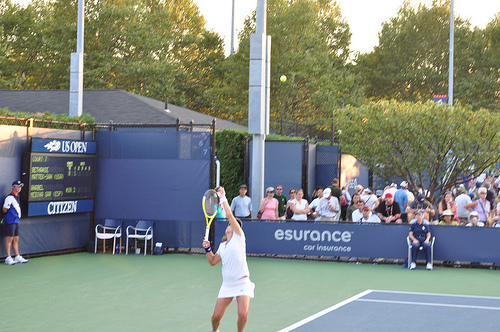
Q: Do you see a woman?
A: Yes, there is a woman.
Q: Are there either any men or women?
A: Yes, there is a woman.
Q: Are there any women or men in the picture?
A: Yes, there is a woman.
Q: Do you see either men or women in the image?
A: Yes, there is a woman.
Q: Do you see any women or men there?
A: Yes, there is a woman.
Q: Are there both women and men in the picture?
A: Yes, there are both a woman and a man.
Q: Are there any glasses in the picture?
A: No, there are no glasses.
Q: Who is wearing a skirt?
A: The woman is wearing a skirt.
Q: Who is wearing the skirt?
A: The woman is wearing a skirt.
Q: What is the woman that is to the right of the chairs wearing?
A: The woman is wearing a skirt.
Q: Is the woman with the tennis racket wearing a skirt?
A: Yes, the woman is wearing a skirt.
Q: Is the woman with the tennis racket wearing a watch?
A: No, the woman is wearing a skirt.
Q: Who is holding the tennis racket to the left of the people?
A: The woman is holding the tennis racket.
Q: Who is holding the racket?
A: The woman is holding the tennis racket.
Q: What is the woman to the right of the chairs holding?
A: The woman is holding the racket.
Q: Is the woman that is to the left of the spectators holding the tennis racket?
A: Yes, the woman is holding the tennis racket.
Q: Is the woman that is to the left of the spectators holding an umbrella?
A: No, the woman is holding the tennis racket.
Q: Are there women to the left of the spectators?
A: Yes, there is a woman to the left of the spectators.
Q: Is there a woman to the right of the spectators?
A: No, the woman is to the left of the spectators.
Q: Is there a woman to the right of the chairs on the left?
A: Yes, there is a woman to the right of the chairs.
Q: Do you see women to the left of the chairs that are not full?
A: No, the woman is to the right of the chairs.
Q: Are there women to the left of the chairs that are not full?
A: No, the woman is to the right of the chairs.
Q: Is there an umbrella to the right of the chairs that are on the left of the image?
A: No, there is a woman to the right of the chairs.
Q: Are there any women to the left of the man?
A: Yes, there is a woman to the left of the man.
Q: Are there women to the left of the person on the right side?
A: Yes, there is a woman to the left of the man.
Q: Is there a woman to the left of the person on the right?
A: Yes, there is a woman to the left of the man.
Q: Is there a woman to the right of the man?
A: No, the woman is to the left of the man.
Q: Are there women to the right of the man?
A: No, the woman is to the left of the man.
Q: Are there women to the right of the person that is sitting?
A: No, the woman is to the left of the man.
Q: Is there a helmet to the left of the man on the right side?
A: No, there is a woman to the left of the man.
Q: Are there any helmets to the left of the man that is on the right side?
A: No, there is a woman to the left of the man.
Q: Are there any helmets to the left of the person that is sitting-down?
A: No, there is a woman to the left of the man.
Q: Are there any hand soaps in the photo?
A: No, there are no hand soaps.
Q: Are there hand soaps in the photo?
A: No, there are no hand soaps.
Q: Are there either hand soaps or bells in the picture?
A: No, there are no hand soaps or bells.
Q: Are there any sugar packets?
A: No, there are no sugar packets.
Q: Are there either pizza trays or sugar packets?
A: No, there are no sugar packets or pizza trays.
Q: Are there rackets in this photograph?
A: Yes, there is a racket.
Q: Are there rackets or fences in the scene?
A: Yes, there is a racket.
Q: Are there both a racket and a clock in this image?
A: No, there is a racket but no clocks.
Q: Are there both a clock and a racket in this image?
A: No, there is a racket but no clocks.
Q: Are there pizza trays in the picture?
A: No, there are no pizza trays.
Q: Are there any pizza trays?
A: No, there are no pizza trays.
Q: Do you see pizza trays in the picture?
A: No, there are no pizza trays.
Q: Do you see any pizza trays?
A: No, there are no pizza trays.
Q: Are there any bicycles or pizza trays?
A: No, there are no pizza trays or bicycles.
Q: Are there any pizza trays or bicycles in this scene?
A: No, there are no pizza trays or bicycles.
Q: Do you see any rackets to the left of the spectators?
A: Yes, there is a racket to the left of the spectators.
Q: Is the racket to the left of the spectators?
A: Yes, the racket is to the left of the spectators.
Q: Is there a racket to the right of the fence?
A: Yes, there is a racket to the right of the fence.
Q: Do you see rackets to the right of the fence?
A: Yes, there is a racket to the right of the fence.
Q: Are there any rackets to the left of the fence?
A: No, the racket is to the right of the fence.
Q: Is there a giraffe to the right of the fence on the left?
A: No, there is a racket to the right of the fence.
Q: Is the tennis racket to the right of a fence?
A: Yes, the tennis racket is to the right of a fence.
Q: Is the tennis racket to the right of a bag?
A: No, the tennis racket is to the right of a fence.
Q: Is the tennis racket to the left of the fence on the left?
A: No, the tennis racket is to the right of the fence.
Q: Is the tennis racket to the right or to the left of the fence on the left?
A: The tennis racket is to the right of the fence.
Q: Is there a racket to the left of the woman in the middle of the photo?
A: Yes, there is a racket to the left of the woman.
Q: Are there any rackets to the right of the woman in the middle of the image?
A: No, the racket is to the left of the woman.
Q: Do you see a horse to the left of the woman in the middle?
A: No, there is a racket to the left of the woman.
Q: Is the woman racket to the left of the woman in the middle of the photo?
A: Yes, the racket is to the left of the woman.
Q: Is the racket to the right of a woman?
A: No, the racket is to the left of a woman.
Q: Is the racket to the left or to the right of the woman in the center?
A: The racket is to the left of the woman.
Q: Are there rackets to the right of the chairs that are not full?
A: Yes, there is a racket to the right of the chairs.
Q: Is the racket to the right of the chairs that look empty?
A: Yes, the racket is to the right of the chairs.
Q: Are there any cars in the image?
A: No, there are no cars.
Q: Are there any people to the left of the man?
A: Yes, there are people to the left of the man.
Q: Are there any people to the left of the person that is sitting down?
A: Yes, there are people to the left of the man.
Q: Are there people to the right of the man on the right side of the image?
A: No, the people are to the left of the man.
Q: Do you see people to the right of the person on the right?
A: No, the people are to the left of the man.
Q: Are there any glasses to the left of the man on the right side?
A: No, there are people to the left of the man.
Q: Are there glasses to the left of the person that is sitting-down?
A: No, there are people to the left of the man.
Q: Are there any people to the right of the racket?
A: Yes, there are people to the right of the racket.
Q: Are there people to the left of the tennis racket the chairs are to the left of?
A: No, the people are to the right of the racket.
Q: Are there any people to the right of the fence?
A: Yes, there are people to the right of the fence.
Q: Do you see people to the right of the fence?
A: Yes, there are people to the right of the fence.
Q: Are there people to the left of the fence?
A: No, the people are to the right of the fence.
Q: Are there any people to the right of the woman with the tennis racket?
A: Yes, there are people to the right of the woman.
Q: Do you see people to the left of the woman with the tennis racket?
A: No, the people are to the right of the woman.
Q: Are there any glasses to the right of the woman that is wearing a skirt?
A: No, there are people to the right of the woman.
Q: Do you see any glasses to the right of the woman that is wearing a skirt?
A: No, there are people to the right of the woman.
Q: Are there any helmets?
A: No, there are no helmets.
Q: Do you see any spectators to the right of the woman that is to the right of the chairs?
A: Yes, there are spectators to the right of the woman.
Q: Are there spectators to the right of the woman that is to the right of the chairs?
A: Yes, there are spectators to the right of the woman.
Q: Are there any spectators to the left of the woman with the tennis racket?
A: No, the spectators are to the right of the woman.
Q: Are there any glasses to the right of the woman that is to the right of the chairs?
A: No, there are spectators to the right of the woman.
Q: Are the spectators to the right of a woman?
A: Yes, the spectators are to the right of a woman.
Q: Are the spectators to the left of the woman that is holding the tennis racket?
A: No, the spectators are to the right of the woman.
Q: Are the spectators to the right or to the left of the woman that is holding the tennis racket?
A: The spectators are to the right of the woman.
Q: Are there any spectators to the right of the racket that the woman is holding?
A: Yes, there are spectators to the right of the tennis racket.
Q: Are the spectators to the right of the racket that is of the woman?
A: Yes, the spectators are to the right of the racket.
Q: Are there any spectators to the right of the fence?
A: Yes, there are spectators to the right of the fence.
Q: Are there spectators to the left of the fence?
A: No, the spectators are to the right of the fence.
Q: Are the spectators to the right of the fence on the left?
A: Yes, the spectators are to the right of the fence.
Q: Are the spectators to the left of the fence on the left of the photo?
A: No, the spectators are to the right of the fence.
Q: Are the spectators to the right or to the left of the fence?
A: The spectators are to the right of the fence.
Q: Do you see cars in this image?
A: No, there are no cars.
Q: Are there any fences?
A: Yes, there is a fence.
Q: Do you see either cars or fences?
A: Yes, there is a fence.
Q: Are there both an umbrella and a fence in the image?
A: No, there is a fence but no umbrellas.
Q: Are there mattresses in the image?
A: No, there are no mattresses.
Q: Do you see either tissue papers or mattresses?
A: No, there are no mattresses or tissue papers.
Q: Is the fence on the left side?
A: Yes, the fence is on the left of the image.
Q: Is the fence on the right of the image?
A: No, the fence is on the left of the image.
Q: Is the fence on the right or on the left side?
A: The fence is on the left of the image.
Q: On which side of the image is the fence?
A: The fence is on the left of the image.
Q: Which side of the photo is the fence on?
A: The fence is on the left of the image.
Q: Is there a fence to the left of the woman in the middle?
A: Yes, there is a fence to the left of the woman.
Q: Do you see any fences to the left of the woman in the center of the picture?
A: Yes, there is a fence to the left of the woman.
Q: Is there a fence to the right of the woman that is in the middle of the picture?
A: No, the fence is to the left of the woman.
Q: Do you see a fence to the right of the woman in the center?
A: No, the fence is to the left of the woman.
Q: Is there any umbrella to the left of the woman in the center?
A: No, there is a fence to the left of the woman.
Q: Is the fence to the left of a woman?
A: Yes, the fence is to the left of a woman.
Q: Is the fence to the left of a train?
A: No, the fence is to the left of a woman.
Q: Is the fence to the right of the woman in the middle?
A: No, the fence is to the left of the woman.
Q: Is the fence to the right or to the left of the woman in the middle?
A: The fence is to the left of the woman.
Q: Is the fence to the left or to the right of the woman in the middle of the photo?
A: The fence is to the left of the woman.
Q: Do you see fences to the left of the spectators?
A: Yes, there is a fence to the left of the spectators.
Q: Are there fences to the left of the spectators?
A: Yes, there is a fence to the left of the spectators.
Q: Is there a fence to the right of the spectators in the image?
A: No, the fence is to the left of the spectators.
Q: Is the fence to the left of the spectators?
A: Yes, the fence is to the left of the spectators.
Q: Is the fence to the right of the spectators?
A: No, the fence is to the left of the spectators.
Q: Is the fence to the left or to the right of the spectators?
A: The fence is to the left of the spectators.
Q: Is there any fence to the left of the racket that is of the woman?
A: Yes, there is a fence to the left of the racket.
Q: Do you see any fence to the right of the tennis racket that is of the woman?
A: No, the fence is to the left of the racket.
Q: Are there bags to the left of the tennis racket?
A: No, there is a fence to the left of the tennis racket.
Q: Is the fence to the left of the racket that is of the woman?
A: Yes, the fence is to the left of the tennis racket.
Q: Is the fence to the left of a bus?
A: No, the fence is to the left of the tennis racket.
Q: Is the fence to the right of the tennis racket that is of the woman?
A: No, the fence is to the left of the tennis racket.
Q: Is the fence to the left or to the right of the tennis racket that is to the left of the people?
A: The fence is to the left of the tennis racket.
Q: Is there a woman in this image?
A: Yes, there is a woman.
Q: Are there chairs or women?
A: Yes, there is a woman.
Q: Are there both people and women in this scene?
A: Yes, there are both a woman and a person.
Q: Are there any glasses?
A: No, there are no glasses.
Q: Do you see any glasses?
A: No, there are no glasses.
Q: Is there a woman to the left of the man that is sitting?
A: Yes, there is a woman to the left of the man.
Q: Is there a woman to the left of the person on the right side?
A: Yes, there is a woman to the left of the man.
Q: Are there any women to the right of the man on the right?
A: No, the woman is to the left of the man.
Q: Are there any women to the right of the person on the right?
A: No, the woman is to the left of the man.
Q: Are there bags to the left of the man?
A: No, there is a woman to the left of the man.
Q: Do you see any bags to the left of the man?
A: No, there is a woman to the left of the man.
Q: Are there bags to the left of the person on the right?
A: No, there is a woman to the left of the man.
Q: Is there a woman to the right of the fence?
A: Yes, there is a woman to the right of the fence.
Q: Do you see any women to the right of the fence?
A: Yes, there is a woman to the right of the fence.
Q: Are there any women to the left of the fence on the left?
A: No, the woman is to the right of the fence.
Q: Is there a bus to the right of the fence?
A: No, there is a woman to the right of the fence.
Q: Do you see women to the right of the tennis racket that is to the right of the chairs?
A: Yes, there is a woman to the right of the racket.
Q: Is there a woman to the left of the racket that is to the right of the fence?
A: No, the woman is to the right of the tennis racket.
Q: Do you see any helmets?
A: No, there are no helmets.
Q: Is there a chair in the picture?
A: Yes, there is a chair.